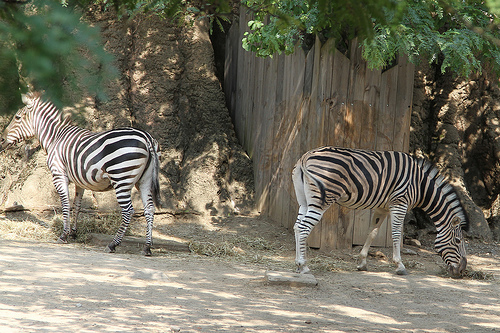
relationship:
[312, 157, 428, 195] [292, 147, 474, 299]
stripes on zebra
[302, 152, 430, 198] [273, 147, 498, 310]
stripes on zebra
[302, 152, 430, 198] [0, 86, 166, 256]
stripes on zebra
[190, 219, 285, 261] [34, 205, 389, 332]
hay on ground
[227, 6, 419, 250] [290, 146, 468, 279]
fence next to zebra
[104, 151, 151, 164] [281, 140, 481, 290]
stripe on zebra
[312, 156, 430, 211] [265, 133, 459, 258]
stripes on zebra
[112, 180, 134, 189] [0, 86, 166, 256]
black stripe on zebra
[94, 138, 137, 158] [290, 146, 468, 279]
stripe on zebra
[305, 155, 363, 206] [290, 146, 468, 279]
stripe on zebra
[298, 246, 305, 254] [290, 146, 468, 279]
stripe on zebra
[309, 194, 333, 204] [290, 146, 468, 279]
stripes on zebra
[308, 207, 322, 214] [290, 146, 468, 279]
stripe on zebra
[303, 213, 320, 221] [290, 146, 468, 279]
stripe on zebra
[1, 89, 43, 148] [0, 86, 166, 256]
head on zebra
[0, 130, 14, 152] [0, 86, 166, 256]
mouth on zebra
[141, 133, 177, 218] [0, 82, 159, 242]
tail on zebra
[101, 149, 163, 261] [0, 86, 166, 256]
legs on zebra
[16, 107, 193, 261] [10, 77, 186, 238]
body on zebra